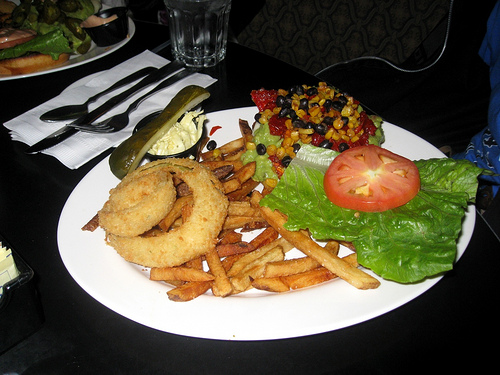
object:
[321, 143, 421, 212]
tomato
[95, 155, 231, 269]
onion rings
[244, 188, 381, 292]
french-fries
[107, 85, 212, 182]
pickle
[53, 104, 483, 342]
plate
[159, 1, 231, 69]
glass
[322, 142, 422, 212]
slice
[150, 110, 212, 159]
coleslaw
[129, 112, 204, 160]
cup